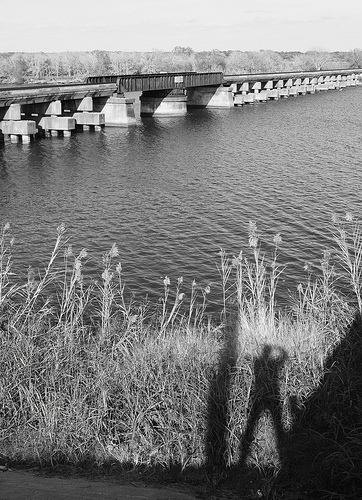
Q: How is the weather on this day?
A: It is cloudy.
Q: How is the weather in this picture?
A: It is cloudy.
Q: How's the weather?
A: It is cloudy.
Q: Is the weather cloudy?
A: Yes, it is cloudy.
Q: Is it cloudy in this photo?
A: Yes, it is cloudy.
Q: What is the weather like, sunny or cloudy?
A: It is cloudy.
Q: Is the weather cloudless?
A: No, it is cloudy.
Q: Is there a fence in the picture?
A: No, there are no fences.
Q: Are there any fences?
A: No, there are no fences.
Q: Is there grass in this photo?
A: Yes, there is grass.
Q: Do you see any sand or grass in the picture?
A: Yes, there is grass.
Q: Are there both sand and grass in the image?
A: No, there is grass but no sand.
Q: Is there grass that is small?
A: Yes, there is small grass.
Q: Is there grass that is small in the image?
A: Yes, there is small grass.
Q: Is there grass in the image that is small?
A: Yes, there is grass that is small.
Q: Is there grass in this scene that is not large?
A: Yes, there is small grass.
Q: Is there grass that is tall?
A: Yes, there is tall grass.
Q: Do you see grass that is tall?
A: Yes, there is grass that is tall.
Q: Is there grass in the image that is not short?
A: Yes, there is tall grass.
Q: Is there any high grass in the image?
A: Yes, there is high grass.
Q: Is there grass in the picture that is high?
A: Yes, there is high grass.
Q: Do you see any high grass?
A: Yes, there is high grass.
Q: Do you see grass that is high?
A: Yes, there is high grass.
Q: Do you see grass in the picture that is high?
A: Yes, there is grass that is high.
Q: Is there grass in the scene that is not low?
A: Yes, there is high grass.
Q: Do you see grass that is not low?
A: Yes, there is high grass.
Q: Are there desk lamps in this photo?
A: No, there are no desk lamps.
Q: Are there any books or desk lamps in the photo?
A: No, there are no desk lamps or books.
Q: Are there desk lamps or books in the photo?
A: No, there are no desk lamps or books.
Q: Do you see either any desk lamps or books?
A: No, there are no desk lamps or books.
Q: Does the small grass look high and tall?
A: Yes, the grass is high and tall.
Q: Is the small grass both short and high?
A: No, the grass is high but tall.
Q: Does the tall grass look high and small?
A: Yes, the grass is high and small.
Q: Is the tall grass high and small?
A: Yes, the grass is high and small.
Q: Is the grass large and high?
A: No, the grass is high but small.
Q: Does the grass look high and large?
A: No, the grass is high but small.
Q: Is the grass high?
A: Yes, the grass is high.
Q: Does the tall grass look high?
A: Yes, the grass is high.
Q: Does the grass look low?
A: No, the grass is high.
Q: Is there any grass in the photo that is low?
A: No, there is grass but it is high.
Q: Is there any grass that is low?
A: No, there is grass but it is high.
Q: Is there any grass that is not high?
A: No, there is grass but it is high.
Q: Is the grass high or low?
A: The grass is high.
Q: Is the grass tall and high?
A: Yes, the grass is tall and high.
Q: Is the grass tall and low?
A: No, the grass is tall but high.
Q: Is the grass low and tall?
A: No, the grass is tall but high.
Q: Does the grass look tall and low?
A: No, the grass is tall but high.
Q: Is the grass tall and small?
A: Yes, the grass is tall and small.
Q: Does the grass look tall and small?
A: Yes, the grass is tall and small.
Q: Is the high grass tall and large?
A: No, the grass is tall but small.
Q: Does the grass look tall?
A: Yes, the grass is tall.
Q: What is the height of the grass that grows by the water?
A: The grass is tall.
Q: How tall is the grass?
A: The grass is tall.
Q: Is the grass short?
A: No, the grass is tall.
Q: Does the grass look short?
A: No, the grass is tall.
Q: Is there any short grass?
A: No, there is grass but it is tall.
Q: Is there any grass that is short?
A: No, there is grass but it is tall.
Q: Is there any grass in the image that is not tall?
A: No, there is grass but it is tall.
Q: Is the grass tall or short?
A: The grass is tall.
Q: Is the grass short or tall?
A: The grass is tall.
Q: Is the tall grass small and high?
A: Yes, the grass is small and high.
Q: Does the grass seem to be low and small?
A: No, the grass is small but high.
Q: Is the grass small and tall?
A: Yes, the grass is small and tall.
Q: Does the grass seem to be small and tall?
A: Yes, the grass is small and tall.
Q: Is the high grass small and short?
A: No, the grass is small but tall.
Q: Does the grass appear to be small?
A: Yes, the grass is small.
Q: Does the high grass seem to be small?
A: Yes, the grass is small.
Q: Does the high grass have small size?
A: Yes, the grass is small.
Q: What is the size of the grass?
A: The grass is small.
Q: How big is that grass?
A: The grass is small.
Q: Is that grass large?
A: No, the grass is small.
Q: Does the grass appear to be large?
A: No, the grass is small.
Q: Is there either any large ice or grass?
A: No, there is grass but it is small.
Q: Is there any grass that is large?
A: No, there is grass but it is small.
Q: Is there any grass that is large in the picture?
A: No, there is grass but it is small.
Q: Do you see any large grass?
A: No, there is grass but it is small.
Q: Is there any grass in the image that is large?
A: No, there is grass but it is small.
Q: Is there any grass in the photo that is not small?
A: No, there is grass but it is small.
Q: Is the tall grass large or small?
A: The grass is small.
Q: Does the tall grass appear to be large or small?
A: The grass is small.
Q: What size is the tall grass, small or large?
A: The grass is small.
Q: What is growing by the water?
A: The grass is growing by the water.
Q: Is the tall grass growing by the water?
A: Yes, the grass is growing by the water.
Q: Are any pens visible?
A: No, there are no pens.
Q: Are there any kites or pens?
A: No, there are no pens or kites.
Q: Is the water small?
A: Yes, the water is small.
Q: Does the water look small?
A: Yes, the water is small.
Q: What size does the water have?
A: The water has small size.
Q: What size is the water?
A: The water is small.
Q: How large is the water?
A: The water is small.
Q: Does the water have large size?
A: No, the water is small.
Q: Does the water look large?
A: No, the water is small.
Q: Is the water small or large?
A: The water is small.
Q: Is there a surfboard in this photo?
A: No, there are no surfboards.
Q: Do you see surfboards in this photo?
A: No, there are no surfboards.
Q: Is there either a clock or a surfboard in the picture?
A: No, there are no surfboards or clocks.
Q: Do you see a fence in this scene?
A: No, there are no fences.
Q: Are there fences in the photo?
A: No, there are no fences.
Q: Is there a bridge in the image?
A: Yes, there is a bridge.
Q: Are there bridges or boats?
A: Yes, there is a bridge.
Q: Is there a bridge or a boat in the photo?
A: Yes, there is a bridge.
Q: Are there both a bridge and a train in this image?
A: No, there is a bridge but no trains.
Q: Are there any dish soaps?
A: No, there are no dish soaps.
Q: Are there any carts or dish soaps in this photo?
A: No, there are no dish soaps or carts.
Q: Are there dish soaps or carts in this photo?
A: No, there are no dish soaps or carts.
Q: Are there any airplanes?
A: No, there are no airplanes.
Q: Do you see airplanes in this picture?
A: No, there are no airplanes.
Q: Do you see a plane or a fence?
A: No, there are no airplanes or fences.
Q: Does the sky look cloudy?
A: Yes, the sky is cloudy.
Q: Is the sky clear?
A: No, the sky is cloudy.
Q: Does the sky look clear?
A: No, the sky is cloudy.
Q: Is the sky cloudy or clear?
A: The sky is cloudy.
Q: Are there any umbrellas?
A: No, there are no umbrellas.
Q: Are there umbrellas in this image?
A: No, there are no umbrellas.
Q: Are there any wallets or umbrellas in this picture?
A: No, there are no umbrellas or wallets.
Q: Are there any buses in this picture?
A: No, there are no buses.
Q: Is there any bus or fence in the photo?
A: No, there are no buses or fences.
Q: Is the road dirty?
A: Yes, the road is dirty.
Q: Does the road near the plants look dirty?
A: Yes, the road is dirty.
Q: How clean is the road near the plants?
A: The road is dirty.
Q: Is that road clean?
A: No, the road is dirty.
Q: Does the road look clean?
A: No, the road is dirty.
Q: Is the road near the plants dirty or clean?
A: The road is dirty.